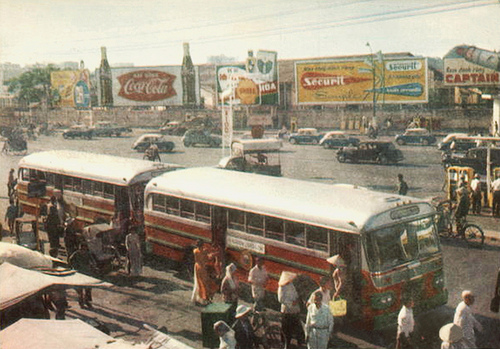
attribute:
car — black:
[335, 140, 405, 163]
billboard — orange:
[294, 55, 429, 105]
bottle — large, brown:
[141, 36, 263, 111]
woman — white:
[185, 239, 235, 281]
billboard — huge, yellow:
[293, 52, 430, 107]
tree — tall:
[6, 57, 72, 105]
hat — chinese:
[325, 251, 347, 266]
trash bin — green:
[201, 296, 239, 346]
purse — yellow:
[324, 294, 348, 321]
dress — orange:
[193, 263, 212, 308]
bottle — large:
[94, 47, 117, 108]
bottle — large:
[181, 44, 198, 107]